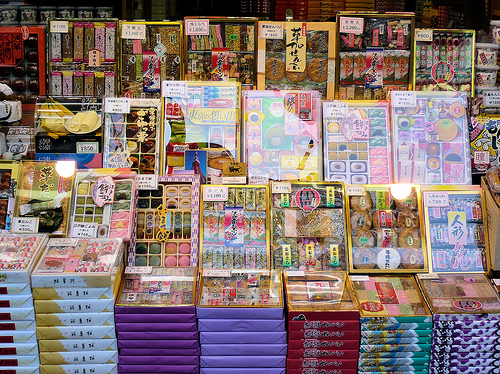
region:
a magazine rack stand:
[6, 8, 481, 361]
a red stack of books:
[293, 309, 359, 366]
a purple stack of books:
[209, 303, 279, 370]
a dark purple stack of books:
[117, 301, 194, 371]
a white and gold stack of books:
[40, 278, 111, 370]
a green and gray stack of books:
[365, 313, 425, 369]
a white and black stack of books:
[423, 317, 498, 371]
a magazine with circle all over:
[396, 88, 468, 186]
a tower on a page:
[190, 153, 211, 178]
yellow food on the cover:
[31, 101, 102, 136]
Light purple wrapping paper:
[196, 306, 285, 321]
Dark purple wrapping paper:
[112, 312, 196, 324]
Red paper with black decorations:
[287, 328, 361, 339]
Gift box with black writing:
[256, 18, 336, 103]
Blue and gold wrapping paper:
[31, 285, 113, 300]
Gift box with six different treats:
[129, 173, 198, 274]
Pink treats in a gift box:
[162, 239, 192, 268]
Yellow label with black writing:
[445, 210, 468, 246]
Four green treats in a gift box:
[132, 239, 162, 268]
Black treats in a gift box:
[135, 180, 166, 210]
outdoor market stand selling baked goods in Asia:
[3, 5, 498, 370]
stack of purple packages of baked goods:
[115, 270, 201, 370]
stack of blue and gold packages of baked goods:
[27, 235, 122, 370]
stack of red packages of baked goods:
[285, 265, 355, 367]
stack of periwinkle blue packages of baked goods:
[191, 266, 281, 366]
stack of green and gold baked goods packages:
[345, 270, 431, 370]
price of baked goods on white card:
[45, 20, 65, 30]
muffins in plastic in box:
[351, 188, 423, 268]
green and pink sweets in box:
[130, 184, 195, 266]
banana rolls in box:
[35, 100, 100, 162]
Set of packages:
[1, 3, 498, 371]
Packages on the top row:
[2, 8, 497, 112]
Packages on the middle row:
[2, 82, 477, 184]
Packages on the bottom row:
[2, 166, 496, 371]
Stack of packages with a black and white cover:
[0, 233, 40, 370]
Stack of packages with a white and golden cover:
[31, 235, 126, 372]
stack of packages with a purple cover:
[114, 272, 199, 370]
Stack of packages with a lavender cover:
[197, 271, 288, 372]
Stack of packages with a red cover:
[284, 268, 359, 372]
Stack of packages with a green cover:
[350, 273, 435, 371]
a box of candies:
[127, 175, 199, 271]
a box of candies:
[201, 181, 269, 268]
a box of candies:
[269, 177, 346, 272]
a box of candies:
[344, 182, 426, 272]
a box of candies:
[423, 190, 488, 272]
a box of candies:
[70, 169, 136, 239]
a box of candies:
[12, 160, 76, 232]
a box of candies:
[103, 95, 157, 190]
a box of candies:
[159, 79, 241, 184]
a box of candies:
[239, 87, 322, 180]